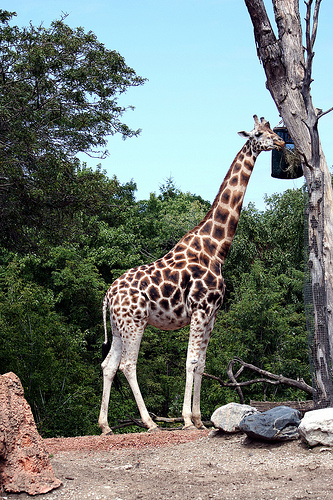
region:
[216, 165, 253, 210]
neck of the giraffe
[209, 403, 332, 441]
rocks on the ground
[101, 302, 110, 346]
the giraffes tail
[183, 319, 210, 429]
the giraffes front legs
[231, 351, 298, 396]
tree branches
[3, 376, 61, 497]
a red rock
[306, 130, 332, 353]
a tree branch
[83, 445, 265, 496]
dirt on the ground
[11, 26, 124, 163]
the green leaves and branches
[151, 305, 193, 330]
the giraffes belly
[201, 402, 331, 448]
THESE ARE STONES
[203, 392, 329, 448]
THE THREE STONES ARE IN A LINE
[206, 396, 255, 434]
THIS STONE IS GREY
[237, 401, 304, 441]
THIS STONE IS BLACK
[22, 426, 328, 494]
THIS IS DIRT COVERING THE GROUND BELOW THE GIRAFFE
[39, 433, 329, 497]
THIS DIRT IS BROWN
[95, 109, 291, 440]
THIS IS A GIRAFFE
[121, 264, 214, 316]
THE GIRAFFE HAS SPOTS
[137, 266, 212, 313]
THE GIRAFFE'S SPOTS ARE BROWN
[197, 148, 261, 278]
THIS GIRAFFE HAS A VERY LONG NECK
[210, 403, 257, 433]
Large rock next to giraffe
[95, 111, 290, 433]
Large giraffe eating hay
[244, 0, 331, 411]
Large tree trunk in front of giraffe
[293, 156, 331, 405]
Mesh fence on tree trunk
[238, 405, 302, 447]
Large rock next to rock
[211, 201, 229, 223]
Large brown spot on giraffe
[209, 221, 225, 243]
Large brown spot on giraffe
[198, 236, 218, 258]
Large brown spot on giraffe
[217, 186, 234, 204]
Large brown spot on giraffe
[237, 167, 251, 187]
Large brown spot on giraffe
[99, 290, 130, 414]
Long hairy tail of giraffe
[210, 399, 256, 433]
Large rock next to rock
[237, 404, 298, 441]
Large rock next to tree trunk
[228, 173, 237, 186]
Large brown spot on giraffe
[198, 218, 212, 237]
Large brown spot on giraffe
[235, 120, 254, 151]
Giraffe has white ear.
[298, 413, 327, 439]
Large gray rock on ground.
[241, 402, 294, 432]
Large gray rock on ground.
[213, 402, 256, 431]
Large gray rock on ground.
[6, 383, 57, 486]
Large brown rock sitting on ground.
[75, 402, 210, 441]
Giraffe standing in the dirt.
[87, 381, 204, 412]
Giraffe has white legs.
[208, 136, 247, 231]
Brown hair down giraffe's neck.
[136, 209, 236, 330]
Giraffe is black, brown, and white.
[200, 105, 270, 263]
Giraffe has long neck.